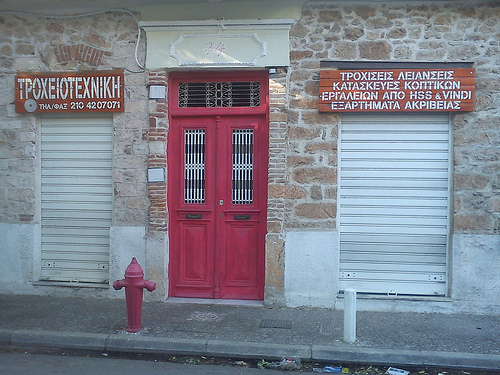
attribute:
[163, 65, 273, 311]
door — red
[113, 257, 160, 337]
fire hydrant — red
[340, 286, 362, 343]
pole — white, small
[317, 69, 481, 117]
sign — brown, wooden, orange, red, white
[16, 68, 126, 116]
sign — brown, wooden, orange, red, white, small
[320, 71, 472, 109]
writing — white, greek, russian, non english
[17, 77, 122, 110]
writing — white, greek, russian, non english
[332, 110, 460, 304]
window — closed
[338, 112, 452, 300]
metal — white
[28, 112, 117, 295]
window — closed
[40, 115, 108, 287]
metal — white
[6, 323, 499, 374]
curb — concrete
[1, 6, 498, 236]
stonework — tan, brick, red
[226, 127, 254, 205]
blind — white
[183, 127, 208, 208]
blind — white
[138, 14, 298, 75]
lintel — white